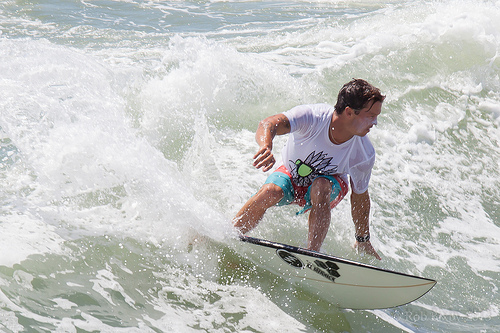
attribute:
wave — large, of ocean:
[15, 17, 498, 218]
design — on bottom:
[275, 247, 340, 284]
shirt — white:
[286, 105, 373, 197]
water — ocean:
[35, 43, 496, 323]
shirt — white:
[285, 112, 367, 189]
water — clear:
[44, 25, 496, 306]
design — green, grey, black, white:
[287, 150, 338, 187]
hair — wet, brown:
[313, 51, 395, 127]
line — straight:
[182, 197, 377, 296]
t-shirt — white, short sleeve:
[285, 103, 372, 196]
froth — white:
[30, 48, 245, 228]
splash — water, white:
[18, 37, 238, 225]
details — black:
[238, 234, 432, 283]